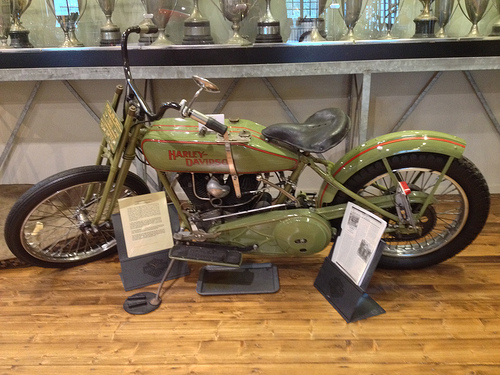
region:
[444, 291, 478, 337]
part of the floor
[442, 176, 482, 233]
part of a rare wheel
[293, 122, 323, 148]
part of a seat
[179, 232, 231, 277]
part of a pedal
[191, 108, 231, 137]
part of a gear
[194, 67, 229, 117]
part of a side mirror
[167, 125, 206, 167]
part of a tank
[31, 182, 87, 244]
part of a front wheel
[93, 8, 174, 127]
part of a steering wheel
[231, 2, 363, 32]
part of some trophies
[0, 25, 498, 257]
A green with a red stripe antique Harley Davidson Motorcycle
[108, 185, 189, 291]
A black document holder with a paper with typed words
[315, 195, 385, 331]
A document holder with a photocopied paper with two photos on it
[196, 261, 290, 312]
A black tray on the wooden floor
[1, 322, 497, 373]
Part of a light brown wooden floor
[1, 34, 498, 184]
A long metal table with a black stripe on the top side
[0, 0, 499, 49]
A table top filled with several trophys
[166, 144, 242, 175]
The words Harley Davidson in red paint on the motorcycle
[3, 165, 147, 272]
The front wheel of the motorcycle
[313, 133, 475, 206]
The back fender on the motorcycle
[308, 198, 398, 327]
Plaque in front of the back tire of the motorcycle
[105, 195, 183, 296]
Plaque next to the front tire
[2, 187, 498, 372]
The hardwood floor the motorcycle is on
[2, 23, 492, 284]
The green and red motorcycle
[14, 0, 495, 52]
Trophies on the shelf in background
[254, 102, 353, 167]
Seat of the motorcycle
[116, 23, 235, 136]
Handle bars of the motorcycle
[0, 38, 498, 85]
Shelf the trophies are on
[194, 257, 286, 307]
Silver pan below the motorcycle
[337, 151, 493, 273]
The back tire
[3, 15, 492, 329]
Vintage Harley-Davidson motorcycle on desplay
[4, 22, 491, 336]
Vintage Harley-Davidson motorcycle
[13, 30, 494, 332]
motorcycle painted olive green with orange pinstriping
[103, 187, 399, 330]
Display information in front of vintage motorcycle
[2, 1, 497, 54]
Trophies being displayed on a shelf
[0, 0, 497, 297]
Trophies being displayed on a shelf behind a motorcycle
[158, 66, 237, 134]
Side mirror on vintage motorcycle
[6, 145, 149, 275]
Chrome wheel on Harley-Davidson motorcycle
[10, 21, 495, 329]
Restored motorcycle on desplay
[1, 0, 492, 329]
Restored motorcycle on display in front of trophies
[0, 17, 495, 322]
green, red, and black motorcycle model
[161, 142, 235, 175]
red text decal saying "Harley Davidson"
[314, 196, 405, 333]
white paper flyer on a metal stand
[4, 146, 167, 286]
black rubber and grey metal wheel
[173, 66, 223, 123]
silver rear view mirror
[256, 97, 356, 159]
black leather motorcycle seat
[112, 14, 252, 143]
black and grey handlebars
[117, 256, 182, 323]
metal kickstand on a black rubber mat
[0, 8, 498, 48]
bottom of many trophies in a display case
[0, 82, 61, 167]
grey metal bar on a tan wall